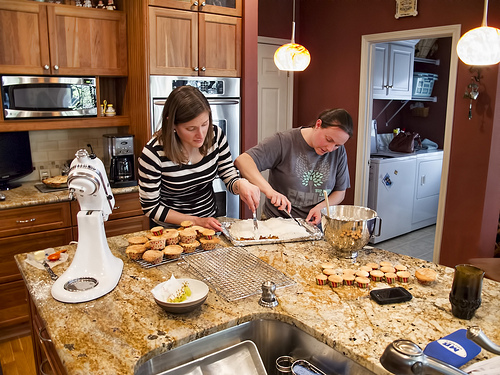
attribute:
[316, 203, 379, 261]
mixing bowl — silver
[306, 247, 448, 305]
cupcakes — several, minature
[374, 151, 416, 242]
washer — white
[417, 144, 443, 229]
dryer — white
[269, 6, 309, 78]
lamp — hanging, glass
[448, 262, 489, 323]
cup — dark, for drink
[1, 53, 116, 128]
microwave — chrome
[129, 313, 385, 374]
sink — metal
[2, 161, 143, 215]
counter — granite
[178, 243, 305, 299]
rack — wire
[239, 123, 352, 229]
shirt — grey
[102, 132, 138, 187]
coffee maker — silver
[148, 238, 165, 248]
muffin — baked , iced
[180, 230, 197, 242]
muffin — baked , iced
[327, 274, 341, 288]
muffin — baked , iced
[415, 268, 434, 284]
muffin — baked , iced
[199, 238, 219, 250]
muffin — baked , iced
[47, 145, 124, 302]
mixer — white, electric, standing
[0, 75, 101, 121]
microwave — shiny, silver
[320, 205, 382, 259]
bowl — silver, shiny, for  mixing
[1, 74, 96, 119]
microwave — silver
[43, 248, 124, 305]
base — white , mixer's